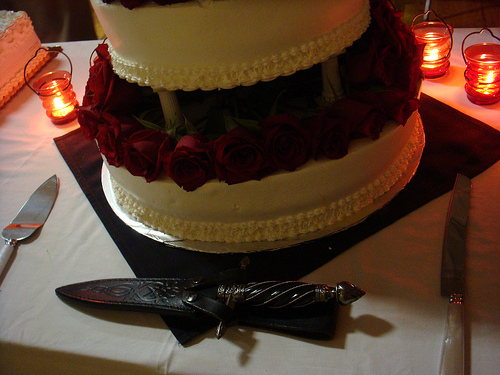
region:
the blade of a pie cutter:
[1, 171, 58, 241]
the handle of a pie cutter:
[0, 240, 16, 285]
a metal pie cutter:
[0, 172, 59, 289]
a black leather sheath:
[57, 275, 223, 319]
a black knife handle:
[213, 281, 367, 341]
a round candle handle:
[21, 47, 73, 99]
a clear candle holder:
[33, 67, 83, 126]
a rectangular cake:
[0, 5, 52, 116]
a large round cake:
[73, 0, 429, 256]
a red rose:
[165, 129, 215, 196]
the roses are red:
[59, 94, 276, 194]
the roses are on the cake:
[77, 97, 307, 177]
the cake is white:
[186, 188, 331, 255]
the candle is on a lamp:
[37, 66, 113, 154]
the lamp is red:
[21, 60, 96, 136]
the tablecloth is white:
[32, 241, 148, 336]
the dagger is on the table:
[78, 280, 380, 361]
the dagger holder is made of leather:
[47, 266, 259, 337]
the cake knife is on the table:
[426, 182, 494, 367]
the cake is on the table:
[19, 60, 450, 339]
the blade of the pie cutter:
[0, 172, 59, 242]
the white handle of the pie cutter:
[0, 237, 15, 276]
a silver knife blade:
[437, 170, 473, 299]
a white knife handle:
[435, 292, 465, 374]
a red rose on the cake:
[161, 134, 213, 194]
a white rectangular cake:
[0, 6, 62, 108]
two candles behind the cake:
[400, 11, 496, 102]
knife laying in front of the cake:
[51, 249, 369, 335]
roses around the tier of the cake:
[73, 61, 405, 186]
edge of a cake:
[3, 4, 71, 111]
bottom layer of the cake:
[83, 89, 428, 239]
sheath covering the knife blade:
[58, 256, 250, 328]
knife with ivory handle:
[435, 155, 480, 372]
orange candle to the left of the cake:
[19, 42, 81, 130]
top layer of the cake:
[78, 0, 379, 78]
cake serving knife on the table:
[3, 160, 61, 339]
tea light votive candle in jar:
[19, 53, 107, 135]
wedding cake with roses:
[73, 5, 411, 275]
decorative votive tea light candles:
[400, 8, 498, 113]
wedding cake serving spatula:
[8, 136, 71, 322]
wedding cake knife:
[426, 142, 494, 372]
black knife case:
[40, 233, 386, 347]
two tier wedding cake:
[85, 26, 436, 276]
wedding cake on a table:
[12, 8, 434, 373]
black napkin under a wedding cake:
[41, 45, 499, 340]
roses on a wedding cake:
[48, 35, 403, 214]